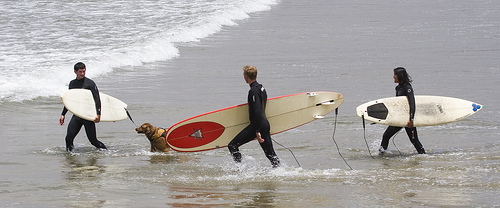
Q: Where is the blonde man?
A: Middle.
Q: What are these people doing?
A: Surfing.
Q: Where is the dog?
A: With man on left.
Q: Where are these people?
A: Beach.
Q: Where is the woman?
A: Far right.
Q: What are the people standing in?
A: Water.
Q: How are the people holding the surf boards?
A: Under their arms.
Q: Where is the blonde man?
A: Middle.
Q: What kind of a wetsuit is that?
A: It is a black wetsuit.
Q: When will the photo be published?
A: Next week.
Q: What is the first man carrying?
A: A white surfboard.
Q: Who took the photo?
A: Jackson Mingus.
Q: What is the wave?
A: White.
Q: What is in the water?
A: Three surfers.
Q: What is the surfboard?
A: Tan and red.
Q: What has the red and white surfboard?
A: The blonde surfer.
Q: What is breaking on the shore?
A: The ocean waves.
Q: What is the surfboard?
A: Red white and black.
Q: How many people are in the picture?
A: Three.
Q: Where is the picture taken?
A: The beach.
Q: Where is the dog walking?
A: Ocean.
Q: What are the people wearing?
A: Wetsuits.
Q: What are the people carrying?
A: Surfboards.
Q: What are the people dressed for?
A: Surfing.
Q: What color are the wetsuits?
A: Black.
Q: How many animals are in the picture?
A: One.